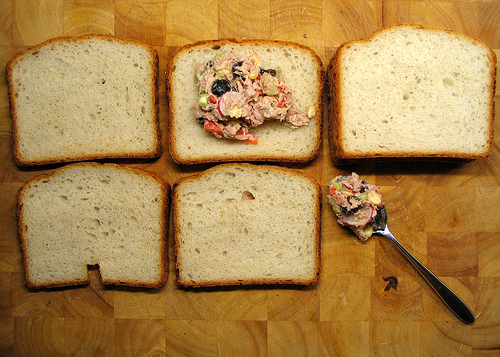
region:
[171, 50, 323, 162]
a piece of bread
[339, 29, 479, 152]
a piece of food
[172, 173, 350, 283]
a piece of butter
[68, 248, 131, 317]
a whole in bread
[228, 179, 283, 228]
mark in the bread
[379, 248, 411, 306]
arrow mark in table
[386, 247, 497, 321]
handle of the spoon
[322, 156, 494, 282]
a spoon on the table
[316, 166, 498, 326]
a spoon near bread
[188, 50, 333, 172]
a pieces in the bread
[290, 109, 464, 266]
a spoon on a table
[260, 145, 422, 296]
a spoon on a table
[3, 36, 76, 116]
bread on a table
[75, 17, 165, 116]
bread on a table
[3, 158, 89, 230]
bread on a table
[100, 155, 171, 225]
bread on a table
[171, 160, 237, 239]
bread on a table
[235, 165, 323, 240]
bread on a table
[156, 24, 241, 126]
pieces of bread on a table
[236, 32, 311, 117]
pieces of bread on a table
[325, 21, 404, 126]
pieces of bread on a table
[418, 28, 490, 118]
pieces of bread on a table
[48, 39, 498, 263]
braed slices aranged on the table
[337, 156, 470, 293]
spoon has cheese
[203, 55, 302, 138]
the slice has some tpopings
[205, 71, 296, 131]
toppings are slightly brown in color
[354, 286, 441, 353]
the floor is brown in color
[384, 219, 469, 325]
the spoon is silvery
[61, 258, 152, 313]
the slice has an open part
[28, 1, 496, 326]
there are four slices of bead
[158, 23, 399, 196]
a pice of bread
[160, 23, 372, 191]
a piece of food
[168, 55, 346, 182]
a piece of hot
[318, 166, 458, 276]
a spoon on table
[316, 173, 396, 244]
a food in spoon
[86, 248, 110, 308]
small whole in bread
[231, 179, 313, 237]
mark in the bread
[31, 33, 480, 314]
a group of breads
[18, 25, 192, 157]
bread on the table